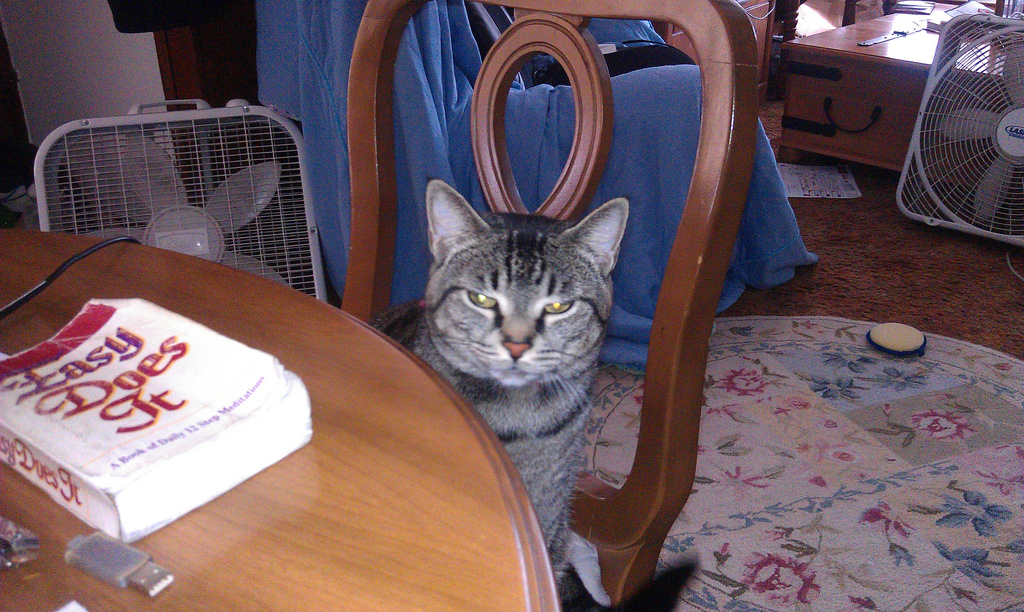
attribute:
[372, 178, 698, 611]
cat — grey, black, gray, angry looking, tabby, small, short-haired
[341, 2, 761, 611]
chair — wooden, dining room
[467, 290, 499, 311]
eye — green, colored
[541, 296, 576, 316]
eye — green, colored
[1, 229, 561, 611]
table — wooden, brown, round, dining room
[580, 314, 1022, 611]
rug — flower patterned, floral, colorful, circular, throw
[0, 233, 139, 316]
cord — black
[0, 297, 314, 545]
book — easy does it, paperback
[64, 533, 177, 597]
usb drive — rectangular, gray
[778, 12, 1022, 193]
chest — wooden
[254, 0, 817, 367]
blanket — blue, throw